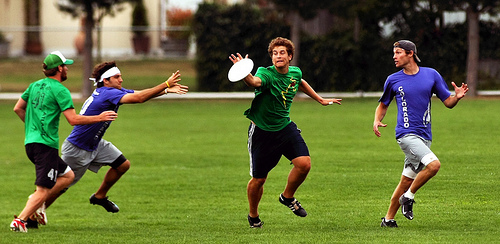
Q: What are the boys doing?
A: Playing.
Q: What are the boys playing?
A: Frisbee.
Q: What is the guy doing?
A: Diving for frisbee.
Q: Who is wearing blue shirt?
A: A man.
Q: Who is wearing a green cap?
A: A man.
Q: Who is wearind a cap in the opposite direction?
A: A man.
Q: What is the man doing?
A: Tring to catch the frisbee.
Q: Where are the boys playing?
A: On the ground.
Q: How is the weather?
A: Sunny and clear.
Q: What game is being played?
A: Frisbee.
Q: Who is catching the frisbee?
A: The man in the green shit and curly hair.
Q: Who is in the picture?
A: Frisbee players.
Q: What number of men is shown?
A: Four.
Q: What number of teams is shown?
A: Two.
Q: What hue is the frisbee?
A: White.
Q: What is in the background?
A: Trees.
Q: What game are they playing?
A: Frisbee.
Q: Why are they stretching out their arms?
A: To catch it.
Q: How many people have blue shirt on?
A: Two.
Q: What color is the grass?
A: Green.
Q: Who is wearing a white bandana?
A: The man in blue.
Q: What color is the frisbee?
A: White.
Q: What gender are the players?
A: Male.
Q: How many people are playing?
A: Four.